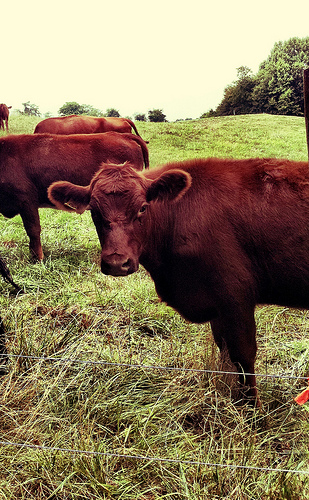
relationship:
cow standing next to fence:
[47, 158, 303, 429] [1, 341, 302, 497]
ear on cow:
[144, 167, 192, 205] [47, 158, 303, 429]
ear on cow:
[36, 163, 114, 211] [48, 155, 292, 248]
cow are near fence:
[47, 158, 309, 410] [1, 341, 302, 497]